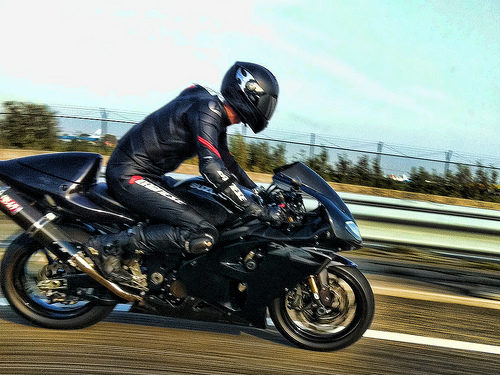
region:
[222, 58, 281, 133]
black helmet of a motor cyclist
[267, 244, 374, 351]
front tire of a moving motorcycle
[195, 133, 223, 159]
red stripe on a black suit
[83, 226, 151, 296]
right boot of a motor cyclist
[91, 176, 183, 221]
black seat of a motor cycle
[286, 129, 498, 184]
bridge in the background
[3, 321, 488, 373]
road under a moving motorcycle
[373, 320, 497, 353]
white stripe on the street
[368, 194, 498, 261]
metal rail guard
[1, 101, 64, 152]
plants alongside the road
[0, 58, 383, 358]
a man riding a motorcycle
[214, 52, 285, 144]
a black and silver motorcycle helmet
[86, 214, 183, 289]
a black motorcycle boot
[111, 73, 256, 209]
a black motorcycle jacket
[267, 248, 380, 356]
a moving front motorcycle tire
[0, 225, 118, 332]
a moving rear motorcycle tire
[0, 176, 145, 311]
motorcycle exhaust pipe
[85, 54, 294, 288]
a man in a seated position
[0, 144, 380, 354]
a black motorcycle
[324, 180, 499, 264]
a metal guard rail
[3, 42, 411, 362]
image of person on motorcycle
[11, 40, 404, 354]
nice image of person on motorcycle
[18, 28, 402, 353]
clear image of person on motorcycle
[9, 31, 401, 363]
good image of person on motorcycle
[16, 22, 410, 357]
person riding on motorcycle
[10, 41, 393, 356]
person riding on nice motorcycle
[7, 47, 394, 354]
person riding on attractive motorcycle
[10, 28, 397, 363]
person riding on shiny motorcycle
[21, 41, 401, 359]
person riding on modern motorcycle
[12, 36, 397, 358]
person riding on great motorcycle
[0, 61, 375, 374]
a man riding a black motorcycle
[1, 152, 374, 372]
a sleek looking black motorcycle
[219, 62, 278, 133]
a man's motorcycle helmet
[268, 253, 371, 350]
the front wheel of a motorcycle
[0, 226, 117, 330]
the rear wheel of a black motorcycle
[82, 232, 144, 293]
a motorcyclist's right boot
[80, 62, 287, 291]
a man riding a motorcycle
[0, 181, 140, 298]
the tailpipe of a motorcycle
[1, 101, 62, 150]
a tree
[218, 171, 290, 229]
a motorcyclist's right glove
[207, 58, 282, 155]
a man weareing a helmet.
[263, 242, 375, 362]
the front wheel of a motorcycle.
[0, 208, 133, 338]
the rear wheel of a motorcycle.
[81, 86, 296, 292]
A man riding a motorcycle down a highway.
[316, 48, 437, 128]
a section of cloud in a blue sky.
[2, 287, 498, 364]
A white line on a road.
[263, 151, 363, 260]
a motorcycle windshield.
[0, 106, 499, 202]
a section of a metal fence.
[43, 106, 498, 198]
A mountain range.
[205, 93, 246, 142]
the neck of a man.